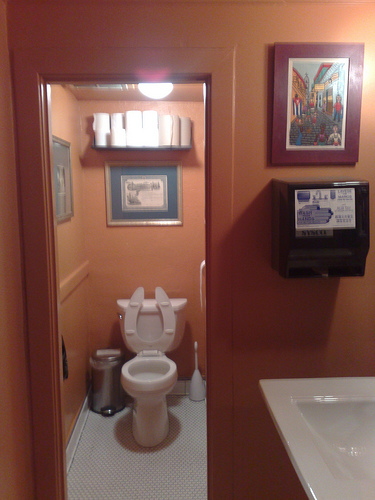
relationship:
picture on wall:
[271, 46, 363, 169] [7, 5, 373, 490]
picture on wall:
[106, 162, 180, 227] [7, 5, 373, 490]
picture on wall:
[44, 141, 76, 220] [7, 5, 373, 490]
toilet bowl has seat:
[108, 289, 194, 457] [120, 286, 179, 353]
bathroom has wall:
[38, 80, 216, 468] [7, 5, 373, 490]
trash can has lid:
[81, 339, 131, 421] [90, 349, 126, 367]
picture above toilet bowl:
[106, 162, 180, 227] [108, 289, 194, 457]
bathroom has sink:
[38, 80, 216, 468] [263, 380, 373, 500]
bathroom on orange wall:
[38, 80, 216, 468] [96, 232, 184, 282]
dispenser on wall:
[251, 172, 372, 282] [218, 65, 373, 326]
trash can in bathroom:
[81, 308, 152, 430] [40, 105, 348, 416]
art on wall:
[256, 33, 369, 144] [223, 11, 373, 176]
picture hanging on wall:
[271, 46, 363, 169] [208, 286, 308, 372]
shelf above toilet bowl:
[88, 138, 192, 154] [108, 289, 194, 457]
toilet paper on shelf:
[81, 107, 195, 150] [88, 138, 192, 154]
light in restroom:
[137, 84, 173, 100] [47, 79, 207, 499]